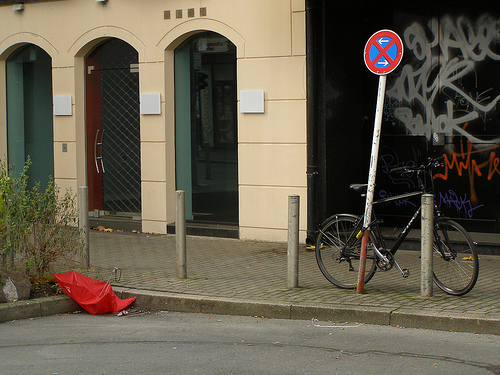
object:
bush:
[11, 216, 88, 298]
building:
[234, 34, 310, 244]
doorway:
[161, 29, 250, 237]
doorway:
[1, 40, 56, 222]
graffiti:
[374, 14, 500, 218]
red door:
[83, 56, 104, 211]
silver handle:
[92, 124, 107, 180]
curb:
[107, 288, 500, 336]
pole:
[352, 27, 406, 294]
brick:
[322, 300, 341, 305]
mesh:
[118, 124, 127, 133]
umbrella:
[28, 233, 193, 373]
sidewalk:
[1, 214, 500, 323]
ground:
[0, 298, 500, 375]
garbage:
[49, 262, 138, 319]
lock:
[355, 217, 379, 240]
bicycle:
[313, 155, 481, 298]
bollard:
[174, 188, 189, 280]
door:
[68, 32, 142, 230]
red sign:
[359, 28, 406, 75]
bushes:
[0, 154, 92, 303]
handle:
[92, 128, 108, 174]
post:
[418, 192, 436, 297]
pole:
[353, 74, 387, 292]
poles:
[283, 195, 301, 288]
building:
[332, 0, 500, 236]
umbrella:
[51, 263, 137, 313]